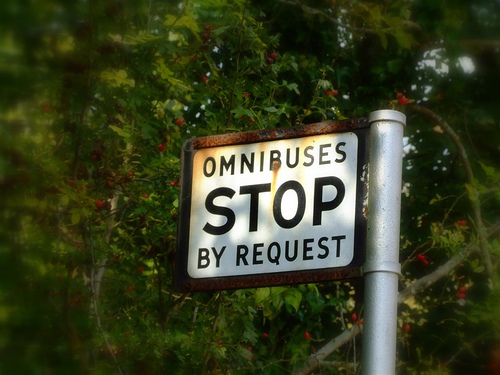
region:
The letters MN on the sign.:
[220, 150, 253, 173]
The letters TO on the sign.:
[236, 177, 306, 237]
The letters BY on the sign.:
[193, 244, 225, 270]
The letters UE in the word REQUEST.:
[286, 237, 316, 263]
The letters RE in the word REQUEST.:
[237, 241, 267, 269]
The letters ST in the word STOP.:
[203, 182, 266, 234]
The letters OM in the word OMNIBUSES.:
[198, 149, 239, 179]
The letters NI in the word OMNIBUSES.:
[241, 149, 263, 172]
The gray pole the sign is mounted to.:
[355, 97, 402, 374]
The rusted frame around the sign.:
[175, 120, 357, 292]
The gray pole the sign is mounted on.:
[355, 101, 415, 371]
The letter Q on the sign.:
[260, 240, 280, 260]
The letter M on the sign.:
[220, 150, 235, 175]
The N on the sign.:
[235, 145, 250, 165]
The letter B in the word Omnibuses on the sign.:
[265, 140, 280, 170]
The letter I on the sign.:
[255, 150, 265, 175]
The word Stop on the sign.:
[196, 170, 341, 235]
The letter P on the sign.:
[310, 172, 350, 228]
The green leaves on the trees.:
[14, 3, 486, 371]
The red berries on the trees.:
[51, 18, 471, 374]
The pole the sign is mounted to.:
[369, 103, 405, 373]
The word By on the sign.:
[198, 245, 229, 265]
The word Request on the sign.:
[232, 230, 349, 268]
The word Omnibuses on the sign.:
[199, 143, 352, 176]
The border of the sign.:
[168, 117, 364, 292]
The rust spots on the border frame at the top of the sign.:
[192, 122, 364, 146]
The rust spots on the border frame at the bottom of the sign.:
[165, 265, 364, 289]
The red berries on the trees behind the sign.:
[20, 45, 486, 369]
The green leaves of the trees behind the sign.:
[15, 3, 497, 365]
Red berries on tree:
[84, 111, 178, 218]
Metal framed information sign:
[175, 120, 365, 294]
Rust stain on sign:
[266, 156, 281, 191]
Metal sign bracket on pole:
[355, 256, 405, 276]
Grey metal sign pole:
[360, 105, 400, 370]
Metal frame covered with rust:
[190, 115, 362, 150]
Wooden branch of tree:
[314, 238, 480, 371]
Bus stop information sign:
[175, 117, 359, 282]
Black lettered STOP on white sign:
[199, 171, 347, 238]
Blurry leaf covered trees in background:
[12, 10, 147, 374]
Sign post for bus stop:
[197, 154, 350, 261]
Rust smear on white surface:
[195, 153, 200, 178]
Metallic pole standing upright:
[375, 148, 387, 253]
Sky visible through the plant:
[465, 62, 472, 69]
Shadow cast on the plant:
[236, 34, 294, 70]